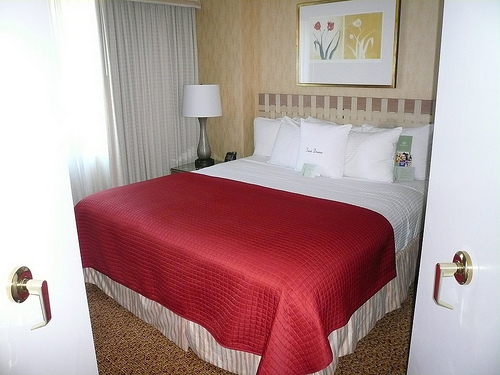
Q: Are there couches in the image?
A: No, there are no couches.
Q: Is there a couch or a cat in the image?
A: No, there are no couches or cats.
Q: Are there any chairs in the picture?
A: No, there are no chairs.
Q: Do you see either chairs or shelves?
A: No, there are no chairs or shelves.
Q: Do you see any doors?
A: Yes, there is a door.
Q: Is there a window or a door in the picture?
A: Yes, there is a door.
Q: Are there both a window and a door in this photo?
A: Yes, there are both a door and a window.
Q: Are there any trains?
A: No, there are no trains.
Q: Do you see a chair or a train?
A: No, there are no trains or chairs.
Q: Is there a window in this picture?
A: Yes, there is a window.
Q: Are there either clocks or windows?
A: Yes, there is a window.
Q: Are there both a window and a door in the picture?
A: Yes, there are both a window and a door.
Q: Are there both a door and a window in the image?
A: Yes, there are both a window and a door.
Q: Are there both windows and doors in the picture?
A: Yes, there are both a window and a door.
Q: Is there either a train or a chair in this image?
A: No, there are no trains or chairs.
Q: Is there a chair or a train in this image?
A: No, there are no trains or chairs.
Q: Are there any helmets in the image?
A: No, there are no helmets.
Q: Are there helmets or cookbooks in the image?
A: No, there are no helmets or cookbooks.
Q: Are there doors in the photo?
A: Yes, there is a door.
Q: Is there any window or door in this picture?
A: Yes, there is a door.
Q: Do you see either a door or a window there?
A: Yes, there is a door.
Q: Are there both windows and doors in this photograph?
A: Yes, there are both a door and a window.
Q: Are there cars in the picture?
A: No, there are no cars.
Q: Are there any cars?
A: No, there are no cars.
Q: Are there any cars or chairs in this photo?
A: No, there are no cars or chairs.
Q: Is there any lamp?
A: Yes, there is a lamp.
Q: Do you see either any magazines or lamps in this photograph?
A: Yes, there is a lamp.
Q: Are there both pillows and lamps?
A: Yes, there are both a lamp and a pillow.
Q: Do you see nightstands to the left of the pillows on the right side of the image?
A: No, there is a lamp to the left of the pillows.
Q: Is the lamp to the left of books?
A: No, the lamp is to the left of the pillows.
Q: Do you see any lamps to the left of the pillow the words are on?
A: Yes, there is a lamp to the left of the pillow.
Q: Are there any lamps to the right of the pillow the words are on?
A: No, the lamp is to the left of the pillow.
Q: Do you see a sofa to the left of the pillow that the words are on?
A: No, there is a lamp to the left of the pillow.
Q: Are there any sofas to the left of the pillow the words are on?
A: No, there is a lamp to the left of the pillow.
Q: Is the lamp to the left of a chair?
A: No, the lamp is to the left of a pillow.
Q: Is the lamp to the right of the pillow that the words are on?
A: No, the lamp is to the left of the pillow.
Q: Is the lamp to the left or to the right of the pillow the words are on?
A: The lamp is to the left of the pillow.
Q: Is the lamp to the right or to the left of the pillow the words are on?
A: The lamp is to the left of the pillow.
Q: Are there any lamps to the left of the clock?
A: Yes, there is a lamp to the left of the clock.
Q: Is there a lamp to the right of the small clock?
A: No, the lamp is to the left of the clock.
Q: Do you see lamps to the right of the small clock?
A: No, the lamp is to the left of the clock.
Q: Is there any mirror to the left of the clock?
A: No, there is a lamp to the left of the clock.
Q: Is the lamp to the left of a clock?
A: Yes, the lamp is to the left of a clock.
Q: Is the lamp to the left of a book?
A: No, the lamp is to the left of a clock.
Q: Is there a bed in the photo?
A: Yes, there is a bed.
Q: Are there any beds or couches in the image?
A: Yes, there is a bed.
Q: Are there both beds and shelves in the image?
A: No, there is a bed but no shelves.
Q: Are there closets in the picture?
A: No, there are no closets.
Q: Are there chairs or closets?
A: No, there are no closets or chairs.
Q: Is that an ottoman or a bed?
A: That is a bed.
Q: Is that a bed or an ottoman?
A: That is a bed.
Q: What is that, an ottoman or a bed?
A: That is a bed.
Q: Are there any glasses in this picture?
A: No, there are no glasses.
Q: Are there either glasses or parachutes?
A: No, there are no glasses or parachutes.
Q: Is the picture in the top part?
A: Yes, the picture is in the top of the image.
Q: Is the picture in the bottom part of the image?
A: No, the picture is in the top of the image.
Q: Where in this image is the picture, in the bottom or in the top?
A: The picture is in the top of the image.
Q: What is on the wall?
A: The picture is on the wall.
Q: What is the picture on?
A: The picture is on the wall.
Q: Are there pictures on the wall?
A: Yes, there is a picture on the wall.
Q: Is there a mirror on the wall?
A: No, there is a picture on the wall.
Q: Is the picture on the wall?
A: Yes, the picture is on the wall.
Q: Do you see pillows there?
A: Yes, there are pillows.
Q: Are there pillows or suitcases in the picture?
A: Yes, there are pillows.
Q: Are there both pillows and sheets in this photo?
A: Yes, there are both pillows and a sheet.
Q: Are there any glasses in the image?
A: No, there are no glasses.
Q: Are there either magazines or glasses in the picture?
A: No, there are no glasses or magazines.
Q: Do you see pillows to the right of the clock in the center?
A: Yes, there are pillows to the right of the clock.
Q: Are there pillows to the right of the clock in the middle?
A: Yes, there are pillows to the right of the clock.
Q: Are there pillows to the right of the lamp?
A: Yes, there are pillows to the right of the lamp.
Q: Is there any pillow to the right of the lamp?
A: Yes, there are pillows to the right of the lamp.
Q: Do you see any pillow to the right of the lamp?
A: Yes, there are pillows to the right of the lamp.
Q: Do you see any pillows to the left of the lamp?
A: No, the pillows are to the right of the lamp.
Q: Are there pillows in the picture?
A: Yes, there is a pillow.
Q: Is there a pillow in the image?
A: Yes, there is a pillow.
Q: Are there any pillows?
A: Yes, there is a pillow.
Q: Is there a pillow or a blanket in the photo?
A: Yes, there is a pillow.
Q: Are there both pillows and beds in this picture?
A: Yes, there are both a pillow and a bed.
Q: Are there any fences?
A: No, there are no fences.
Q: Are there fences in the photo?
A: No, there are no fences.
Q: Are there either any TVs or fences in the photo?
A: No, there are no fences or tvs.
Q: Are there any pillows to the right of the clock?
A: Yes, there is a pillow to the right of the clock.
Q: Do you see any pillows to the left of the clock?
A: No, the pillow is to the right of the clock.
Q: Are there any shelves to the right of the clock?
A: No, there is a pillow to the right of the clock.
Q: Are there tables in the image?
A: Yes, there is a table.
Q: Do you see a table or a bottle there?
A: Yes, there is a table.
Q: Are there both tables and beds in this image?
A: Yes, there are both a table and a bed.